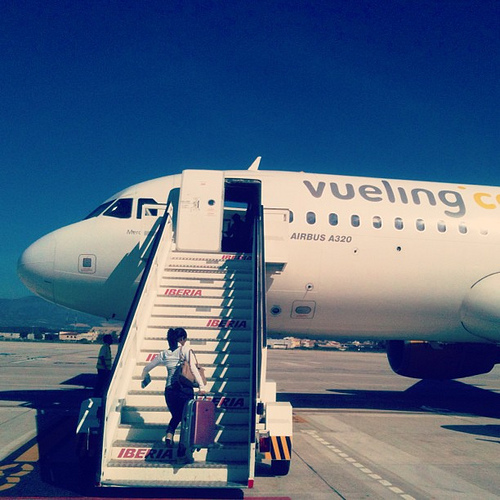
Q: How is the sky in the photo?
A: Clear.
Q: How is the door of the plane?
A: Ajar.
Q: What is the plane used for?
A: Carrying passengers.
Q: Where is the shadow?
A: Under plane.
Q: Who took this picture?
A: A passenger.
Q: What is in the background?
A: Buildings.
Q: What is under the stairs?
A: Wheels.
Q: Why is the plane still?
A: People are loading.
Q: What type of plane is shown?
A: Airbus.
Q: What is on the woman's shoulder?
A: A purse.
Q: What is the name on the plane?
A: Vueling.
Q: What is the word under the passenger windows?
A: Airbus A320.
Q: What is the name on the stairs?
A: Iberia.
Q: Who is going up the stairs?
A: A woman.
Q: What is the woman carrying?
A: A suitcase.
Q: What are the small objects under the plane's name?
A: Passenger windows.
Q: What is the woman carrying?
A: Suitcase.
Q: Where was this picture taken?
A: Airport.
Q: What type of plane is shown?
A: Passenger.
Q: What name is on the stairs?
A: Iberia.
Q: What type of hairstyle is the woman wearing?
A: Ponytail.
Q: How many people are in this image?
A: One.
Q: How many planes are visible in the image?
A: One.